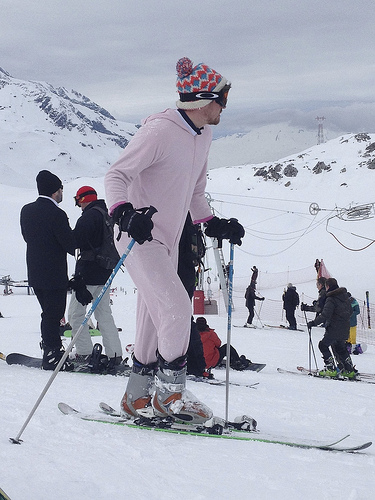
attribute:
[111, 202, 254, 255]
gloves — black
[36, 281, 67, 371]
pants — black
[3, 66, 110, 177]
mountain — grey, white, large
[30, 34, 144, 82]
sky — grey, cold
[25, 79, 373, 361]
people — many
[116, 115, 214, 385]
outfit — pink, one-piece, light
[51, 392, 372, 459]
skis — green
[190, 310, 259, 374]
person — one